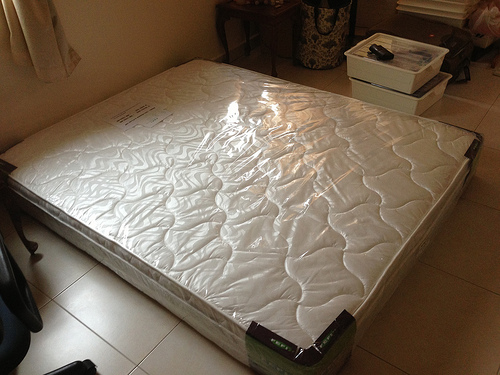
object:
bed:
[2, 59, 485, 374]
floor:
[3, 26, 496, 373]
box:
[348, 71, 453, 114]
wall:
[0, 1, 218, 144]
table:
[214, 0, 301, 77]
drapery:
[1, 0, 81, 83]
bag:
[296, 2, 352, 71]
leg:
[42, 358, 99, 374]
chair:
[0, 238, 97, 375]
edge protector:
[245, 309, 358, 375]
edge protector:
[438, 119, 484, 189]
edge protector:
[175, 58, 222, 67]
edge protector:
[0, 139, 25, 177]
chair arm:
[0, 237, 44, 333]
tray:
[395, 6, 479, 21]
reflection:
[219, 82, 295, 150]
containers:
[343, 33, 449, 95]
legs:
[214, 2, 231, 64]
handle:
[430, 59, 443, 70]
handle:
[433, 82, 447, 97]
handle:
[313, 3, 339, 36]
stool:
[0, 182, 38, 255]